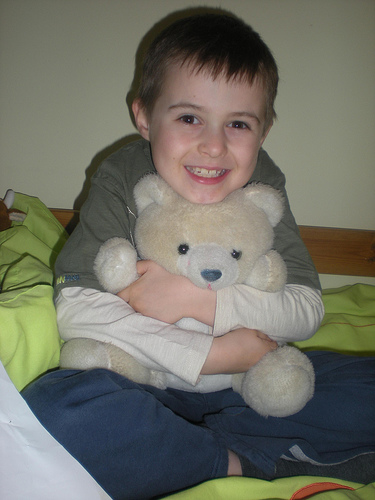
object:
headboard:
[0, 0, 375, 277]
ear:
[132, 169, 170, 216]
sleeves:
[54, 286, 214, 386]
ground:
[307, 52, 357, 94]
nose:
[198, 241, 225, 282]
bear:
[60, 171, 315, 419]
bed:
[0, 188, 375, 500]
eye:
[229, 248, 242, 261]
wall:
[331, 1, 374, 164]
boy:
[18, 5, 374, 500]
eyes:
[177, 242, 191, 255]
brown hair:
[134, 5, 280, 138]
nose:
[197, 121, 228, 158]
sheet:
[0, 188, 375, 499]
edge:
[289, 481, 354, 500]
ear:
[132, 97, 151, 142]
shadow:
[49, 4, 235, 289]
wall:
[5, 3, 61, 159]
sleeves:
[213, 270, 326, 342]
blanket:
[0, 187, 375, 500]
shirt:
[53, 138, 326, 388]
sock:
[231, 452, 375, 485]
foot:
[270, 452, 374, 485]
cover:
[0, 314, 375, 500]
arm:
[55, 286, 278, 374]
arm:
[116, 260, 326, 343]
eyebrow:
[168, 101, 203, 111]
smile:
[177, 144, 244, 196]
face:
[150, 68, 268, 204]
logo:
[56, 273, 80, 286]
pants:
[19, 341, 375, 500]